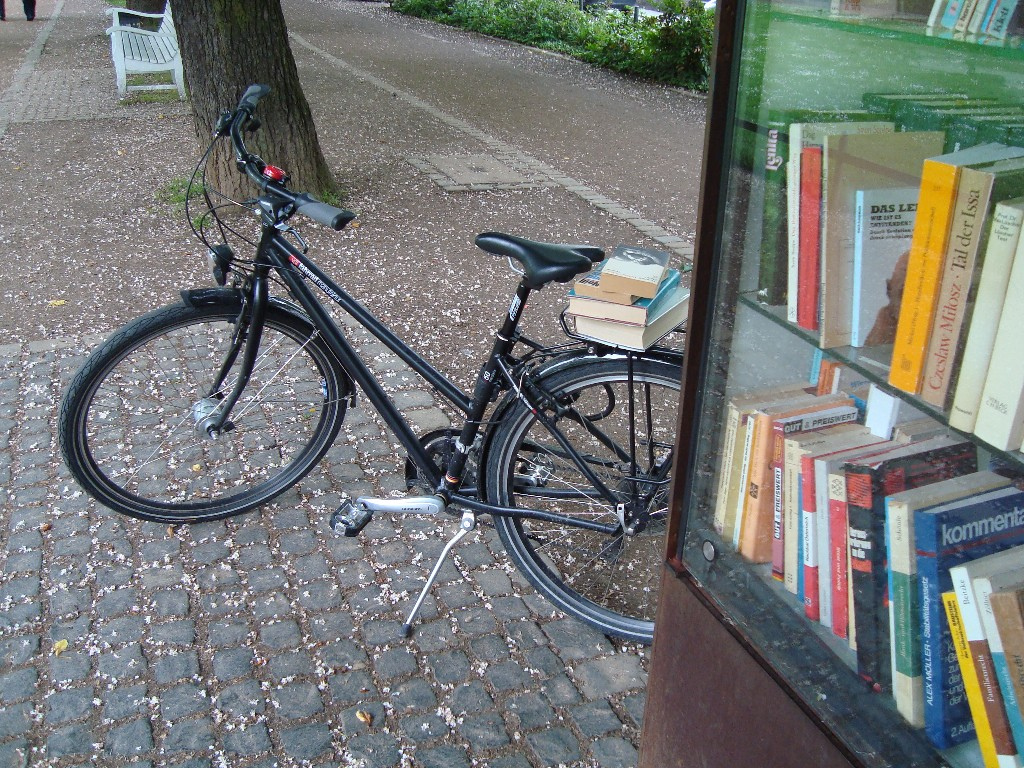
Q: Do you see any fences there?
A: No, there are no fences.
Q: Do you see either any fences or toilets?
A: No, there are no fences or toilets.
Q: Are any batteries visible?
A: No, there are no batteries.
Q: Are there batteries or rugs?
A: No, there are no batteries or rugs.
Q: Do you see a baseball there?
A: No, there are no baseballs.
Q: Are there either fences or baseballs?
A: No, there are no baseballs or fences.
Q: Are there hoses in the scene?
A: No, there are no hoses.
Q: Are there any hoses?
A: No, there are no hoses.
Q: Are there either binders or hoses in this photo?
A: No, there are no hoses or binders.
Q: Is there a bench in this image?
A: Yes, there is a bench.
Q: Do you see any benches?
A: Yes, there is a bench.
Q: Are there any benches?
A: Yes, there is a bench.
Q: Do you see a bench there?
A: Yes, there is a bench.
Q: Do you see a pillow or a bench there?
A: Yes, there is a bench.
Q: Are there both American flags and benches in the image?
A: No, there is a bench but no American flags.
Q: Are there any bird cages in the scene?
A: No, there are no bird cages.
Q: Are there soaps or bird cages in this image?
A: No, there are no bird cages or soaps.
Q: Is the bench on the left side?
A: Yes, the bench is on the left of the image.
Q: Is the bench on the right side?
A: No, the bench is on the left of the image.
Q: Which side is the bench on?
A: The bench is on the left of the image.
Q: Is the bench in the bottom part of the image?
A: No, the bench is in the top of the image.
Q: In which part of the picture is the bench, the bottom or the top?
A: The bench is in the top of the image.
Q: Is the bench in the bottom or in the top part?
A: The bench is in the top of the image.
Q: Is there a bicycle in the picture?
A: Yes, there is a bicycle.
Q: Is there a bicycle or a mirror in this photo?
A: Yes, there is a bicycle.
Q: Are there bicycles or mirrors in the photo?
A: Yes, there is a bicycle.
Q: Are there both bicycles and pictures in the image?
A: No, there is a bicycle but no pictures.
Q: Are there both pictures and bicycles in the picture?
A: No, there is a bicycle but no pictures.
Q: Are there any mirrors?
A: No, there are no mirrors.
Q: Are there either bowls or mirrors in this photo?
A: No, there are no mirrors or bowls.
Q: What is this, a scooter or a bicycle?
A: This is a bicycle.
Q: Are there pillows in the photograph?
A: No, there are no pillows.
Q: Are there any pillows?
A: No, there are no pillows.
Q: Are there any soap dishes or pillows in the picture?
A: No, there are no pillows or soap dishes.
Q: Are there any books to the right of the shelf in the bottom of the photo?
A: Yes, there is a book to the right of the shelf.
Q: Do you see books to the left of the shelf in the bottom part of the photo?
A: No, the book is to the right of the shelf.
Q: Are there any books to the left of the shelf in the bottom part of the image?
A: No, the book is to the right of the shelf.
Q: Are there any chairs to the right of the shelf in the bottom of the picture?
A: No, there is a book to the right of the shelf.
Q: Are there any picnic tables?
A: No, there are no picnic tables.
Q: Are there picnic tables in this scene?
A: No, there are no picnic tables.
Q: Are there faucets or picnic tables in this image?
A: No, there are no picnic tables or faucets.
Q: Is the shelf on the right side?
A: Yes, the shelf is on the right of the image.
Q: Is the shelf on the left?
A: No, the shelf is on the right of the image.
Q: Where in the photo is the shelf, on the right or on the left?
A: The shelf is on the right of the image.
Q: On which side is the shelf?
A: The shelf is on the right of the image.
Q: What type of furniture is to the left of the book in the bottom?
A: The piece of furniture is a shelf.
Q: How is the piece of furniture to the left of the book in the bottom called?
A: The piece of furniture is a shelf.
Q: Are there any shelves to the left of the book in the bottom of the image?
A: Yes, there is a shelf to the left of the book.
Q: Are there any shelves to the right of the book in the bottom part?
A: No, the shelf is to the left of the book.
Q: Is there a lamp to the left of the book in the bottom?
A: No, there is a shelf to the left of the book.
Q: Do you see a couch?
A: No, there are no couches.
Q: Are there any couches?
A: No, there are no couches.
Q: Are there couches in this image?
A: No, there are no couches.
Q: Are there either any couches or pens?
A: No, there are no couches or pens.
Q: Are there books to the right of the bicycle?
A: Yes, there is a book to the right of the bicycle.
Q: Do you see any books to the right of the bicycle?
A: Yes, there is a book to the right of the bicycle.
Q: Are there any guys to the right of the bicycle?
A: No, there is a book to the right of the bicycle.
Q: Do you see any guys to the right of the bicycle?
A: No, there is a book to the right of the bicycle.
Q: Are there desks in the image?
A: No, there are no desks.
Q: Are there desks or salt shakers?
A: No, there are no desks or salt shakers.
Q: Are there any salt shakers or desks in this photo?
A: No, there are no desks or salt shakers.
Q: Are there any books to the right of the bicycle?
A: Yes, there is a book to the right of the bicycle.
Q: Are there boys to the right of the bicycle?
A: No, there is a book to the right of the bicycle.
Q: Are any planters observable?
A: No, there are no planters.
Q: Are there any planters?
A: No, there are no planters.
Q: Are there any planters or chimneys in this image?
A: No, there are no planters or chimneys.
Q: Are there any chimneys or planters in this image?
A: No, there are no planters or chimneys.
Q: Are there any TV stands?
A: No, there are no TV stands.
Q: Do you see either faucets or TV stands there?
A: No, there are no TV stands or faucets.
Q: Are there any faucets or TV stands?
A: No, there are no TV stands or faucets.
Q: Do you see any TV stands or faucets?
A: No, there are no TV stands or faucets.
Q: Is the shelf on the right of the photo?
A: Yes, the shelf is on the right of the image.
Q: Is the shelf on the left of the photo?
A: No, the shelf is on the right of the image.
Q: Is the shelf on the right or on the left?
A: The shelf is on the right of the image.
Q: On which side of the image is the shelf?
A: The shelf is on the right of the image.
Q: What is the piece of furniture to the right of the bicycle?
A: The piece of furniture is a shelf.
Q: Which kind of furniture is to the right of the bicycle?
A: The piece of furniture is a shelf.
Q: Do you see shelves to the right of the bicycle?
A: Yes, there is a shelf to the right of the bicycle.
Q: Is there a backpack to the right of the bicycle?
A: No, there is a shelf to the right of the bicycle.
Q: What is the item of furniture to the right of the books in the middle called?
A: The piece of furniture is a shelf.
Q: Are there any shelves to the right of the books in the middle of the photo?
A: Yes, there is a shelf to the right of the books.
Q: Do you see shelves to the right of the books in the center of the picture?
A: Yes, there is a shelf to the right of the books.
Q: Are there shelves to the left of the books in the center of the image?
A: No, the shelf is to the right of the books.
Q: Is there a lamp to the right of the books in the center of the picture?
A: No, there is a shelf to the right of the books.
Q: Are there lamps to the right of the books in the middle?
A: No, there is a shelf to the right of the books.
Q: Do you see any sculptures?
A: No, there are no sculptures.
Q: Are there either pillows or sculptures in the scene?
A: No, there are no sculptures or pillows.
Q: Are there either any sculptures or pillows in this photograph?
A: No, there are no sculptures or pillows.